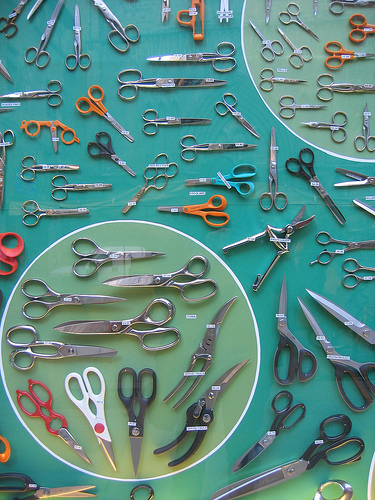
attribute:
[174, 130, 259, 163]
scissor — small, silver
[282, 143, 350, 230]
scissor — small, silver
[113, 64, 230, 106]
scissor — small, silver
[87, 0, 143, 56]
scissor — small, silver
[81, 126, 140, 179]
scissor — small, silver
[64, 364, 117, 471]
scissors — white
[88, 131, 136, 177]
scissors — orange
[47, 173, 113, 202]
scissors — metal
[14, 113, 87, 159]
scissors — small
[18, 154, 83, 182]
scissors — metal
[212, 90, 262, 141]
scissors — small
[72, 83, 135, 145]
scissors — black, green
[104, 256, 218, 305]
scissors — metal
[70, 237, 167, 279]
scissors — metal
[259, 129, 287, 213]
scissors — metal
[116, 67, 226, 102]
scissors — metal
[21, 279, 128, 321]
scissors — metal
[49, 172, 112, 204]
scissors — small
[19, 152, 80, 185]
scissors — silver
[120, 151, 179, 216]
double scissors — blue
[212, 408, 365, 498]
large scissors — black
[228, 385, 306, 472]
small scissors — black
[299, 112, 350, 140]
scissors — needlenosed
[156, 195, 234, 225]
scissors — green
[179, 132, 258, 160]
scissors — green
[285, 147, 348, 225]
scissors — green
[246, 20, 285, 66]
scissors — green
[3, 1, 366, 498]
mat — blue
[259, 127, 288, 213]
sizzors — metal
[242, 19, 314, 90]
scissors. — small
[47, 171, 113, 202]
sizzors — metal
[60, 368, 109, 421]
handle — orange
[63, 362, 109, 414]
handle — red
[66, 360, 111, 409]
handle — white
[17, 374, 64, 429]
handle — oddly shaped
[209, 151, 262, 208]
handle — blue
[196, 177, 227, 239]
handle — orange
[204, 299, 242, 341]
blade — curved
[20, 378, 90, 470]
scissors — white, red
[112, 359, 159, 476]
scissors — black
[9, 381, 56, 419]
handles — red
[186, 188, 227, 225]
handles — orange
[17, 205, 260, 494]
circle — green